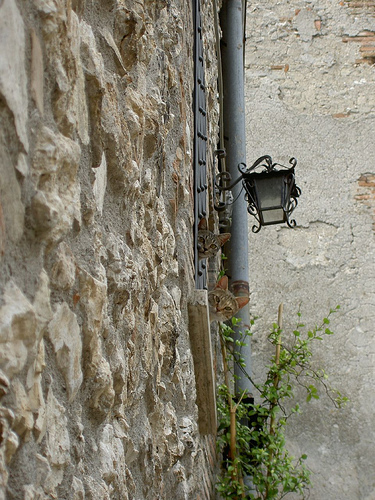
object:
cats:
[191, 210, 230, 263]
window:
[192, 0, 213, 296]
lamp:
[236, 156, 302, 234]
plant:
[210, 299, 349, 498]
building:
[151, 173, 193, 258]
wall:
[271, 12, 366, 73]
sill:
[203, 30, 217, 64]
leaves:
[292, 326, 300, 336]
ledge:
[186, 288, 217, 436]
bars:
[242, 0, 247, 77]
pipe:
[224, 53, 247, 174]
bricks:
[290, 222, 319, 233]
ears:
[217, 229, 232, 250]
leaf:
[265, 320, 280, 348]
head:
[196, 215, 232, 260]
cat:
[206, 273, 253, 325]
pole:
[211, 0, 227, 190]